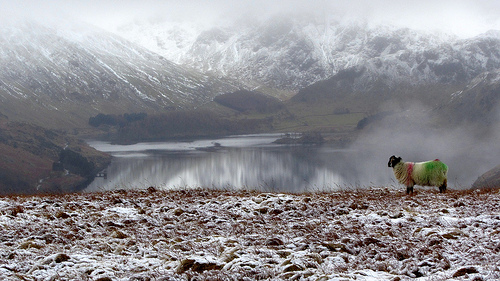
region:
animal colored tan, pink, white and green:
[371, 136, 457, 207]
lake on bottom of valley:
[77, 116, 427, 202]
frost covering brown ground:
[81, 191, 448, 267]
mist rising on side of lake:
[356, 101, 476, 196]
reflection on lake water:
[90, 137, 345, 197]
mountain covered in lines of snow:
[5, 10, 165, 130]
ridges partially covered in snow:
[180, 5, 335, 100]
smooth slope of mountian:
[80, 25, 270, 105]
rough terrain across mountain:
[236, 10, 371, 75]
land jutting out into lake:
[258, 107, 366, 162]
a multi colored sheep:
[387, 155, 448, 195]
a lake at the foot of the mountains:
[83, 133, 488, 190]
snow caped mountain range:
[1, 0, 499, 94]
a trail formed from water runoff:
[60, 27, 157, 102]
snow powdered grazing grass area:
[0, 187, 499, 278]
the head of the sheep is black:
[388, 153, 400, 167]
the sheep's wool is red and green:
[398, 157, 447, 187]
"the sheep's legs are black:
[407, 183, 414, 194]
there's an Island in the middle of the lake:
[195, 141, 238, 154]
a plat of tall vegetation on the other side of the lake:
[215, 88, 285, 114]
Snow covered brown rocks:
[1, 210, 155, 279]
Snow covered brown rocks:
[156, 231, 296, 279]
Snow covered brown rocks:
[291, 202, 439, 256]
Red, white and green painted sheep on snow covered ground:
[373, 145, 473, 217]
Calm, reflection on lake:
[120, 143, 366, 193]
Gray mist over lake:
[366, 58, 498, 145]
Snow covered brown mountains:
[8, 4, 162, 109]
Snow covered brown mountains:
[134, 10, 356, 102]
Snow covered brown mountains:
[343, 10, 497, 107]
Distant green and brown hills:
[166, 83, 351, 130]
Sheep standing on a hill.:
[383, 151, 446, 192]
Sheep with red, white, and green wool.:
[385, 152, 449, 195]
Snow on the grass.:
[15, 195, 480, 265]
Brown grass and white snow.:
[40, 200, 250, 275]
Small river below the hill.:
[105, 140, 285, 180]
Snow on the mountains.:
[0, 0, 495, 115]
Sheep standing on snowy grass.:
[350, 150, 475, 245]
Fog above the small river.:
[335, 90, 470, 180]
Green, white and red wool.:
[400, 155, 440, 185]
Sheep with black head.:
[380, 150, 402, 170]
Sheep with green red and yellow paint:
[373, 150, 454, 191]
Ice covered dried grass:
[87, 195, 375, 266]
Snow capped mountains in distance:
[43, 37, 325, 72]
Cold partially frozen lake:
[129, 148, 294, 176]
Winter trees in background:
[130, 116, 242, 133]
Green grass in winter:
[294, 108, 351, 125]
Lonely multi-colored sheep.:
[379, 145, 459, 194]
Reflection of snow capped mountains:
[192, 162, 328, 187]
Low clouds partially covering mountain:
[66, 9, 151, 46]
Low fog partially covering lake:
[380, 124, 468, 151]